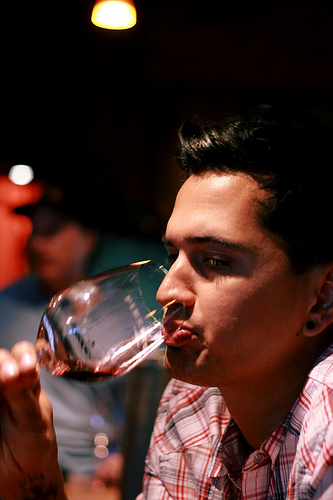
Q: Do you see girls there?
A: No, there are no girls.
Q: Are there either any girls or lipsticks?
A: No, there are no girls or lipsticks.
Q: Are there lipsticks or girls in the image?
A: No, there are no girls or lipsticks.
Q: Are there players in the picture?
A: No, there are no players.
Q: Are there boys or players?
A: No, there are no players or boys.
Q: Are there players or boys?
A: No, there are no players or boys.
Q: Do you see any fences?
A: No, there are no fences.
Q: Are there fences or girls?
A: No, there are no fences or girls.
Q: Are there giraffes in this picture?
A: No, there are no giraffes.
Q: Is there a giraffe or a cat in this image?
A: No, there are no giraffes or cats.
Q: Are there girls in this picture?
A: No, there are no girls.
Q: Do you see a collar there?
A: Yes, there is a collar.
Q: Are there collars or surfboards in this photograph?
A: Yes, there is a collar.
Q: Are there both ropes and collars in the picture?
A: No, there is a collar but no ropes.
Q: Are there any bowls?
A: No, there are no bowls.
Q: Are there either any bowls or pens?
A: No, there are no bowls or pens.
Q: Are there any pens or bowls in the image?
A: No, there are no bowls or pens.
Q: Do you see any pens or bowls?
A: No, there are no bowls or pens.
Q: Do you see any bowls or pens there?
A: No, there are no bowls or pens.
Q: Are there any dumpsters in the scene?
A: No, there are no dumpsters.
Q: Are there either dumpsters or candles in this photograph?
A: No, there are no dumpsters or candles.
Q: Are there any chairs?
A: No, there are no chairs.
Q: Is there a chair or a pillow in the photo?
A: No, there are no chairs or pillows.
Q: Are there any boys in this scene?
A: No, there are no boys.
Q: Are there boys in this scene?
A: No, there are no boys.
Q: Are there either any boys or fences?
A: No, there are no boys or fences.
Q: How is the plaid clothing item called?
A: The clothing item is a shirt.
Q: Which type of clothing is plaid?
A: The clothing is a shirt.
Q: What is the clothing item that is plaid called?
A: The clothing item is a shirt.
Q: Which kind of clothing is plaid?
A: The clothing is a shirt.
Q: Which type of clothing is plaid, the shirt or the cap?
A: The shirt is plaid.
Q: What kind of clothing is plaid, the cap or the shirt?
A: The shirt is plaid.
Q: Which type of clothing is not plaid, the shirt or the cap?
A: The cap is not plaid.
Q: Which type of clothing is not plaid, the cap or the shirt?
A: The cap is not plaid.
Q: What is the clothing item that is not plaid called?
A: The clothing item is a cap.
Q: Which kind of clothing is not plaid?
A: The clothing is a cap.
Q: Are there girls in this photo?
A: No, there are no girls.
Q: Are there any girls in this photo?
A: No, there are no girls.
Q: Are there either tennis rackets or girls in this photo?
A: No, there are no girls or tennis rackets.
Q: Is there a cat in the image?
A: No, there are no cats.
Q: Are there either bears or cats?
A: No, there are no cats or bears.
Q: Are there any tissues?
A: No, there are no tissues.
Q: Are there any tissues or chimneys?
A: No, there are no tissues or chimneys.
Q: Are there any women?
A: No, there are no women.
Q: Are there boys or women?
A: No, there are no women or boys.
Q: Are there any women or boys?
A: No, there are no women or boys.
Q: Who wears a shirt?
A: The man wears a shirt.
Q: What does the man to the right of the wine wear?
A: The man wears a shirt.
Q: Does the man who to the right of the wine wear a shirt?
A: Yes, the man wears a shirt.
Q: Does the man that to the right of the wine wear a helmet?
A: No, the man wears a shirt.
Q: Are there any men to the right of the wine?
A: Yes, there is a man to the right of the wine.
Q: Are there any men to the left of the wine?
A: No, the man is to the right of the wine.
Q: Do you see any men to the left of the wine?
A: No, the man is to the right of the wine.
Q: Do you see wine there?
A: Yes, there is wine.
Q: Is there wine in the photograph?
A: Yes, there is wine.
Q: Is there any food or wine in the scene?
A: Yes, there is wine.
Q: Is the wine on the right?
A: No, the wine is on the left of the image.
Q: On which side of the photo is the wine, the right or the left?
A: The wine is on the left of the image.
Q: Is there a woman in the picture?
A: No, there are no women.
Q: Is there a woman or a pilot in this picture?
A: No, there are no women or pilots.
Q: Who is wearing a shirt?
A: The man is wearing a shirt.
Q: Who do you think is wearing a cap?
A: The man is wearing a cap.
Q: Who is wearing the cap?
A: The man is wearing a cap.